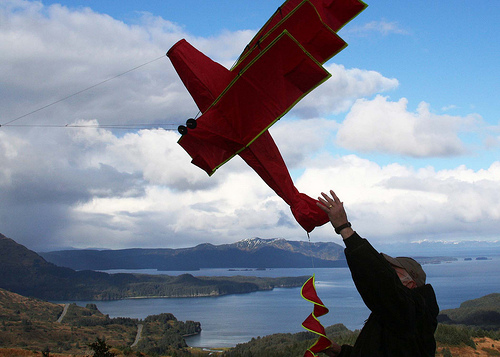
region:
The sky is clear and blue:
[403, 8, 490, 96]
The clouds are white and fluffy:
[349, 176, 484, 225]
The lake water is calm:
[208, 288, 303, 322]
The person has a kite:
[122, 20, 460, 352]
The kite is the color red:
[151, 3, 333, 240]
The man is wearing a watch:
[329, 213, 357, 236]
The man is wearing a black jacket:
[338, 230, 441, 355]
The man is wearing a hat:
[378, 241, 431, 287]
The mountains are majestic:
[4, 233, 311, 353]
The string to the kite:
[11, 48, 159, 150]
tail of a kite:
[288, 276, 338, 355]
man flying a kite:
[317, 188, 454, 344]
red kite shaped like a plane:
[143, 0, 372, 239]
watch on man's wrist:
[329, 217, 356, 234]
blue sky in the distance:
[412, 43, 478, 90]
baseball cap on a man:
[379, 244, 439, 286]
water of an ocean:
[198, 300, 288, 328]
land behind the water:
[183, 235, 340, 279]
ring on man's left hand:
[321, 198, 338, 213]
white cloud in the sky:
[339, 98, 459, 158]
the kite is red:
[138, 13, 361, 240]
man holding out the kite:
[301, 158, 423, 349]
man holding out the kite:
[174, 45, 426, 354]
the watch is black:
[316, 199, 366, 249]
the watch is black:
[286, 148, 396, 288]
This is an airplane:
[174, 59, 295, 254]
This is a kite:
[138, 64, 415, 249]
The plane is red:
[148, 59, 348, 186]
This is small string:
[16, 76, 148, 150]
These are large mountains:
[150, 203, 320, 278]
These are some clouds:
[115, 203, 251, 253]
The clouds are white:
[106, 144, 215, 236]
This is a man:
[330, 231, 420, 335]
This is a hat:
[382, 221, 462, 291]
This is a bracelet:
[309, 226, 367, 243]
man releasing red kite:
[164, 27, 439, 355]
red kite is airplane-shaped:
[163, 27, 348, 237]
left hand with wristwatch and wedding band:
[313, 189, 354, 235]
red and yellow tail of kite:
[298, 269, 335, 355]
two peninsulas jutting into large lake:
[0, 237, 499, 356]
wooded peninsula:
[0, 232, 312, 301]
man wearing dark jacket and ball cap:
[315, 189, 441, 355]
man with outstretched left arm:
[316, 187, 443, 355]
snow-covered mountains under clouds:
[355, 159, 498, 256]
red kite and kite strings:
[1, 27, 346, 244]